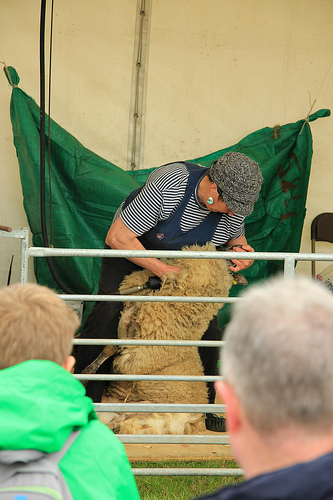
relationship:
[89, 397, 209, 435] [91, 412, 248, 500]
wool on top of ground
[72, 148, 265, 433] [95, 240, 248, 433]
woman shearing sheep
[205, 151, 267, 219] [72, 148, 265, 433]
hat of woman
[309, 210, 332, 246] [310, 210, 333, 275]
part of a chair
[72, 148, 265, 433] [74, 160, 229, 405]
woman wearing overalls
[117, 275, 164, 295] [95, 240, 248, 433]
shear used for shearing sheep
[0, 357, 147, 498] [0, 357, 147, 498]
boy wearing jacket